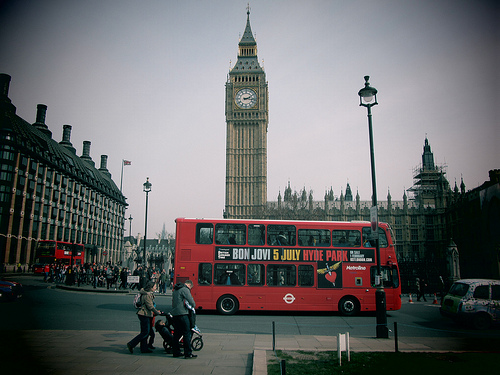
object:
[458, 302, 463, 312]
light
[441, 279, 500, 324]
car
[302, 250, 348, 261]
hyde park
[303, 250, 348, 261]
lettering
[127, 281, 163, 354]
people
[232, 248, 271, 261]
bon jovi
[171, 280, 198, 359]
people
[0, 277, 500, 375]
ground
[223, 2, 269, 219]
big ben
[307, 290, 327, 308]
red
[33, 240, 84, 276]
bus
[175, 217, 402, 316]
bus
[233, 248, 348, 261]
text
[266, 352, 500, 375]
grass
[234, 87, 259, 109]
face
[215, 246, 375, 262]
poster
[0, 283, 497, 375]
street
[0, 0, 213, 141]
sky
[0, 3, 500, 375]
outside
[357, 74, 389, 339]
street lamp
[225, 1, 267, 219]
tower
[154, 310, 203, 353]
stroller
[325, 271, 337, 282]
heart